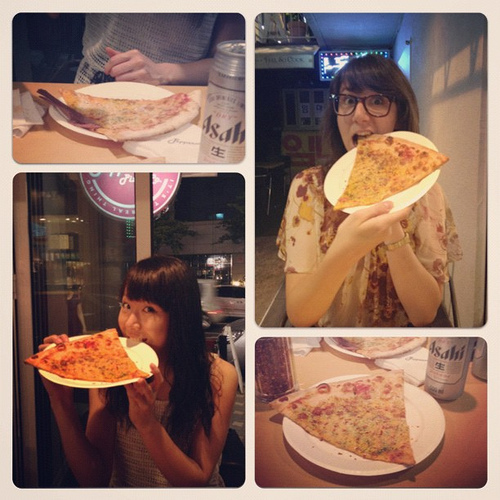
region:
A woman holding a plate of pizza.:
[276, 53, 463, 325]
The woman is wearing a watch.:
[383, 230, 410, 252]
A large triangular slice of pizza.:
[265, 368, 420, 466]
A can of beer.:
[424, 335, 476, 399]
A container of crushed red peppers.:
[255, 335, 296, 400]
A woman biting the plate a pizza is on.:
[28, 255, 238, 489]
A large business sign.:
[77, 173, 183, 216]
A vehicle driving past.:
[199, 283, 244, 328]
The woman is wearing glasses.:
[330, 91, 394, 117]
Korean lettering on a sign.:
[279, 129, 334, 168]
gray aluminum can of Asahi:
[424, 337, 471, 400]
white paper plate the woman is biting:
[36, 334, 158, 389]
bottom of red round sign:
[80, 172, 181, 218]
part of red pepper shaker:
[256, 338, 298, 402]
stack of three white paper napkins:
[12, 88, 45, 135]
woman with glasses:
[273, 53, 462, 325]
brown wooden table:
[13, 82, 208, 162]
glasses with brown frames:
[331, 92, 394, 117]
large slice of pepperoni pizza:
[26, 328, 149, 382]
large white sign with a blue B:
[298, 101, 308, 117]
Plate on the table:
[271, 358, 449, 483]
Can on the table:
[417, 328, 481, 409]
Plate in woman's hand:
[22, 321, 165, 411]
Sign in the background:
[68, 161, 188, 222]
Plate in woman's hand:
[322, 126, 445, 260]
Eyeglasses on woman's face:
[323, 89, 400, 122]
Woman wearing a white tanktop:
[60, 241, 231, 486]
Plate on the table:
[17, 68, 204, 154]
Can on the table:
[180, 29, 255, 169]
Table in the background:
[252, 131, 298, 229]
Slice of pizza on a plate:
[267, 369, 445, 477]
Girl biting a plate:
[24, 249, 238, 483]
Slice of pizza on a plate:
[25, 327, 158, 396]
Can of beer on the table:
[421, 332, 476, 402]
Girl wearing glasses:
[326, 56, 421, 153]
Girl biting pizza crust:
[318, 56, 449, 226]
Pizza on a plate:
[46, 78, 199, 145]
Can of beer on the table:
[198, 37, 245, 159]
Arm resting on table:
[103, 39, 224, 84]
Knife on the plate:
[36, 85, 96, 130]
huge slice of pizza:
[27, 326, 146, 396]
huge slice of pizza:
[268, 360, 426, 465]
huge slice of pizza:
[332, 121, 448, 218]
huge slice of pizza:
[50, 59, 203, 148]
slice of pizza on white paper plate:
[23, 324, 164, 392]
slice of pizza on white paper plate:
[272, 371, 449, 476]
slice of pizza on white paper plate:
[320, 125, 450, 222]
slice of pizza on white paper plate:
[31, 64, 205, 145]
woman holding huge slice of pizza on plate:
[25, 236, 239, 478]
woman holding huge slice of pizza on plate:
[279, 49, 451, 328]